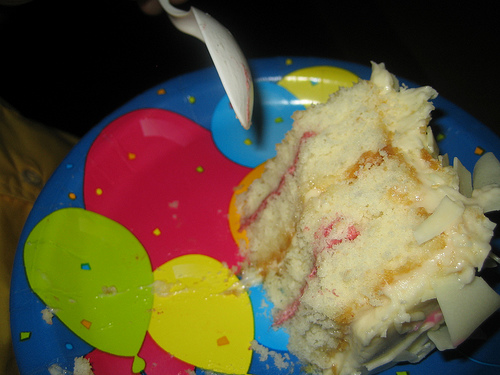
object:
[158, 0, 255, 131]
spoon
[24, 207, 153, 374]
balloon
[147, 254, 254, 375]
balloon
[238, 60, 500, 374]
cake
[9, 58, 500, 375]
plate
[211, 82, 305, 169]
balloon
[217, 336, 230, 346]
speck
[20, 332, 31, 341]
speck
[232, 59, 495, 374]
frosting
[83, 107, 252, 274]
pink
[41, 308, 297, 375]
crumbs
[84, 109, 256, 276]
balloon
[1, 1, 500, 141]
dark area